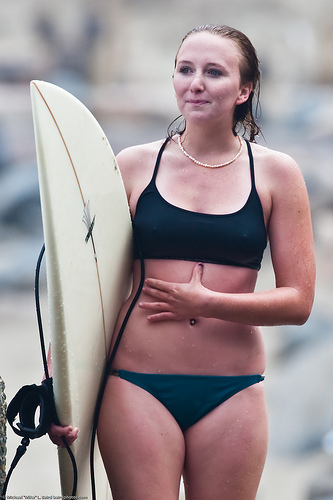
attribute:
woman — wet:
[122, 31, 255, 488]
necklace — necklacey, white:
[179, 150, 243, 167]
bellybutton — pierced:
[189, 318, 194, 327]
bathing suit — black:
[135, 197, 259, 415]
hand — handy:
[149, 289, 185, 317]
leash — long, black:
[116, 311, 126, 354]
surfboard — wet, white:
[63, 155, 113, 329]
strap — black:
[33, 255, 41, 301]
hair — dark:
[248, 62, 255, 74]